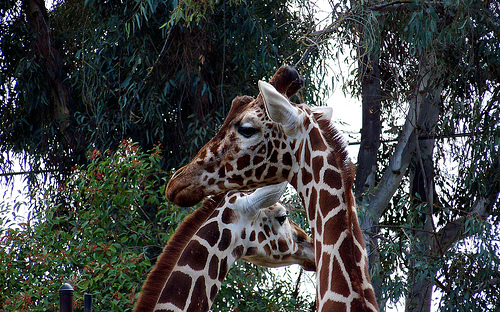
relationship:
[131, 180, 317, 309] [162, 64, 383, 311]
giraffe next to giraffe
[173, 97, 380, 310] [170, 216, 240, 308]
giraffe has spots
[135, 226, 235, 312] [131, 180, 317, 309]
giraffe's neck part of giraffe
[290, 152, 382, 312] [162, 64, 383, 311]
giraffe's neck part of giraffe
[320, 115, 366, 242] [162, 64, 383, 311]
mane part of giraffe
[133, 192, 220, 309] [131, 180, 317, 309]
mane part of giraffe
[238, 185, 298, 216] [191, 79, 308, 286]
ear part of giraffe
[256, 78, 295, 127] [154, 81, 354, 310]
ear part of giraffe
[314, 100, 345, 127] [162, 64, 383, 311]
ear part of giraffe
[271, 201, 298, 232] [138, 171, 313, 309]
eye part of giraffe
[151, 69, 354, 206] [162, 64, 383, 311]
head part of giraffe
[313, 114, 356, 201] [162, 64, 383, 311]
mane part of giraffe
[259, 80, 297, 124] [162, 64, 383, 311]
ear part of giraffe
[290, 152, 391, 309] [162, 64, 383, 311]
giraffe's neck part of giraffe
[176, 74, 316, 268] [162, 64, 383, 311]
giraffe's head part of giraffe